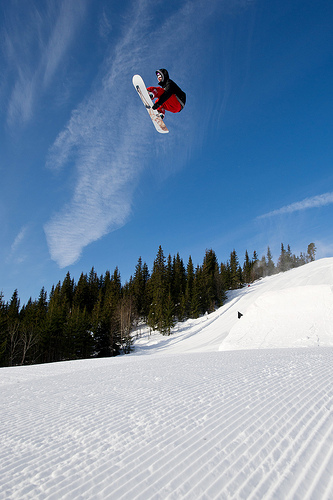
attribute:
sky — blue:
[1, 2, 330, 287]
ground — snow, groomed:
[1, 257, 330, 500]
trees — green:
[1, 238, 314, 365]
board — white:
[131, 76, 168, 134]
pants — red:
[148, 88, 182, 120]